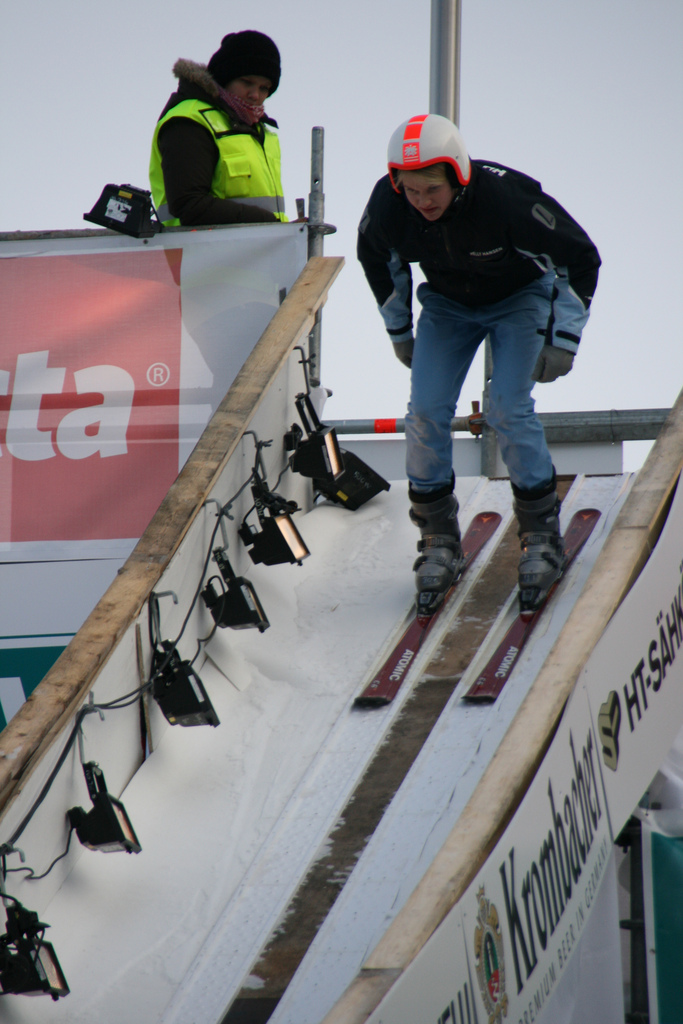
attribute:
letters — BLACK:
[509, 821, 554, 927]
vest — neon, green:
[120, 93, 314, 232]